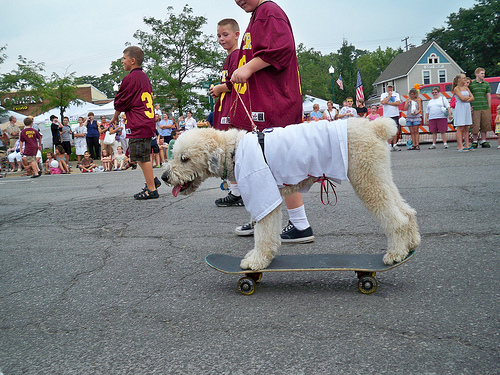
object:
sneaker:
[235, 218, 257, 235]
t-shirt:
[233, 118, 346, 222]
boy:
[231, 1, 318, 244]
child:
[27, 145, 129, 176]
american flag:
[355, 70, 366, 107]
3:
[141, 88, 155, 119]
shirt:
[112, 69, 163, 136]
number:
[141, 92, 155, 119]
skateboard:
[203, 246, 416, 296]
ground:
[315, 205, 379, 242]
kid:
[109, 47, 161, 200]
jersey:
[114, 67, 156, 138]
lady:
[424, 85, 450, 150]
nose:
[160, 172, 171, 182]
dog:
[160, 117, 422, 270]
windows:
[421, 51, 449, 87]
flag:
[354, 70, 366, 109]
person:
[80, 110, 105, 161]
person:
[70, 112, 87, 169]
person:
[44, 112, 67, 152]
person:
[447, 69, 477, 154]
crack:
[88, 212, 137, 242]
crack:
[42, 232, 119, 312]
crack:
[130, 185, 199, 223]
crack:
[313, 225, 499, 238]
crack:
[350, 315, 498, 357]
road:
[0, 136, 498, 373]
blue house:
[368, 40, 468, 140]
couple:
[453, 62, 494, 156]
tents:
[0, 98, 132, 155]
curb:
[392, 132, 477, 154]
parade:
[94, 1, 425, 296]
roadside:
[399, 142, 482, 172]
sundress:
[454, 90, 474, 128]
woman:
[425, 87, 451, 149]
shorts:
[426, 118, 446, 134]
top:
[428, 97, 449, 120]